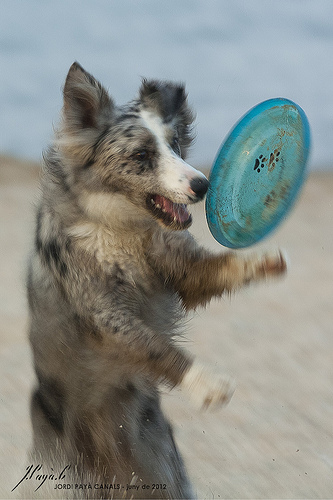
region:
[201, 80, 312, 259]
blue frisbee in the air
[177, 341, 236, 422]
blurry white paw on a dog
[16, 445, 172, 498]
black copy wright on a photograph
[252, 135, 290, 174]
two black paws painted on a frisbee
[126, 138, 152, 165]
dark eye on a dog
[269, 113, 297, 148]
dirt and sand on a frisbee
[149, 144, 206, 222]
white snout on a dog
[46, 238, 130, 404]
grey and black fur on a dog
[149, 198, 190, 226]
open mouth of a dog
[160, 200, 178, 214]
pink tongue of a dog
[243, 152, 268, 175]
black paw prints on frisbee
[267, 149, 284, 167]
black paw print on frisbee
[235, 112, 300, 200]
sand on front of frisbee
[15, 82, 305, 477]
dog jumping for frisbee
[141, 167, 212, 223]
open mouth of dog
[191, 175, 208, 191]
black nose of a dog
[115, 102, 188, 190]
white and black face of a dog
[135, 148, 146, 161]
black eye of dog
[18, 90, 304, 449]
australian shepherd jumping for firsbee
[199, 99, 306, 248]
The frisbee is blue.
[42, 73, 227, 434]
The dog is jumping.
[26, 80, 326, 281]
The dog is biting the frisbee.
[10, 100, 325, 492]
The dog is on the beach.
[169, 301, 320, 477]
The sand is brown.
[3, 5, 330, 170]
The water is blue.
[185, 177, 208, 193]
His nose is black.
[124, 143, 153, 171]
His eye is black.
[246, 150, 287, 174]
The paw prints are black.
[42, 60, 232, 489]
He is gray.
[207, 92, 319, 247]
blue frisbee being caught by dog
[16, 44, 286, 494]
brown fuzzy dog with white paws and chest playing frisbee on beach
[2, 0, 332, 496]
sunny daytime beach scene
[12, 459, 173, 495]
black writing on picture indicating photographer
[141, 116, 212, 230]
dog's open mouth and white snout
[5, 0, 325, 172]
clear bright sunny blue sky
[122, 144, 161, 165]
amber eye with black pupil of dog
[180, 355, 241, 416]
white paw on brown dog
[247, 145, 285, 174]
black paw prints on blue frisbee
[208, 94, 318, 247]
wet sand on blue frisbee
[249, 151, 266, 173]
black dog paw print on frisbee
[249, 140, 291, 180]
two black paw print images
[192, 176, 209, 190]
black nose of dog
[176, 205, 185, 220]
orange tongue of dog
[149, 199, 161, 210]
white teeth of dog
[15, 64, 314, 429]
australian shepherd jumping for frisbee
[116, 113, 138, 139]
black spots on head of dog